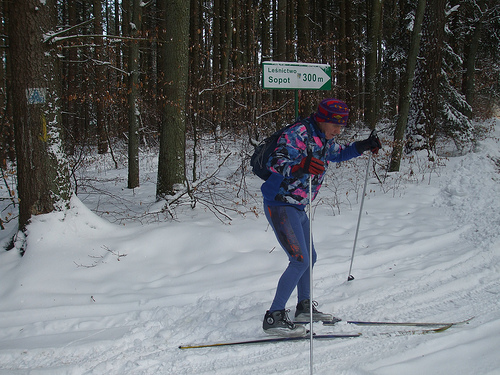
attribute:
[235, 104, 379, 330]
woman — skiing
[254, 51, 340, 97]
sign — white, green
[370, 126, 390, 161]
glove — red, black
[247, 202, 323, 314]
pants — blue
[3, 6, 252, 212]
trees — leafless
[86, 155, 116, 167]
leaves — dead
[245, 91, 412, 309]
lady — old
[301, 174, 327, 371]
stick — thin, long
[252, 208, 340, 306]
stockings — blue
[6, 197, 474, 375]
snow — white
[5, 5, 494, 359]
picture — taken